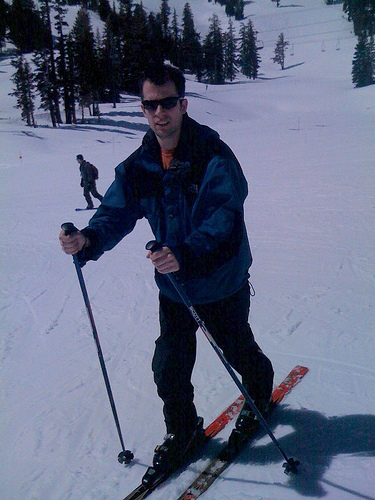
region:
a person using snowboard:
[61, 88, 303, 484]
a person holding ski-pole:
[53, 221, 148, 466]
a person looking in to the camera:
[132, 65, 197, 146]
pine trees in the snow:
[30, 3, 286, 104]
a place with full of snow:
[278, 100, 340, 301]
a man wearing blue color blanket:
[102, 138, 257, 298]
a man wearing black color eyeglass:
[132, 90, 188, 110]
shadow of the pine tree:
[100, 114, 136, 132]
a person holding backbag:
[69, 153, 109, 210]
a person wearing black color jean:
[147, 289, 270, 420]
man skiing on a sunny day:
[76, 67, 305, 491]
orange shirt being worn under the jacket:
[147, 139, 181, 173]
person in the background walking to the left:
[69, 147, 112, 220]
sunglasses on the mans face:
[135, 95, 187, 109]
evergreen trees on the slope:
[12, 4, 262, 109]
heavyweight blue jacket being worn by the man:
[84, 137, 261, 299]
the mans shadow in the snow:
[246, 402, 368, 494]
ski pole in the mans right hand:
[61, 221, 133, 469]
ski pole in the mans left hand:
[145, 240, 300, 476]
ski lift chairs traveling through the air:
[251, 12, 361, 60]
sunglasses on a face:
[143, 96, 184, 110]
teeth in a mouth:
[154, 121, 173, 129]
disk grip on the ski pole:
[116, 447, 138, 465]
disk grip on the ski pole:
[276, 456, 311, 480]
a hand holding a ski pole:
[142, 240, 180, 280]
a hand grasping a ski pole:
[44, 213, 85, 256]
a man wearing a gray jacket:
[49, 141, 106, 206]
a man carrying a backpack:
[66, 143, 108, 206]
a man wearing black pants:
[55, 56, 291, 458]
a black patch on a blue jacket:
[131, 165, 154, 198]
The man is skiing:
[99, 343, 328, 498]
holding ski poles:
[141, 245, 317, 456]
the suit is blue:
[122, 162, 251, 270]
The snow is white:
[266, 82, 351, 297]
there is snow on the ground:
[249, 110, 354, 326]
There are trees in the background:
[9, 9, 272, 122]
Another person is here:
[54, 140, 119, 259]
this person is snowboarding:
[51, 142, 126, 245]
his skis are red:
[170, 376, 287, 497]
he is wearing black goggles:
[141, 86, 183, 120]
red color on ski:
[204, 403, 232, 430]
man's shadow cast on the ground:
[305, 395, 358, 463]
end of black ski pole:
[107, 450, 136, 465]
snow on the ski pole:
[192, 460, 240, 481]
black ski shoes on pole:
[146, 397, 212, 471]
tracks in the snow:
[278, 288, 333, 332]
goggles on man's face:
[132, 97, 199, 113]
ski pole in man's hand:
[62, 218, 130, 472]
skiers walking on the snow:
[44, 63, 277, 337]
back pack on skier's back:
[82, 158, 103, 180]